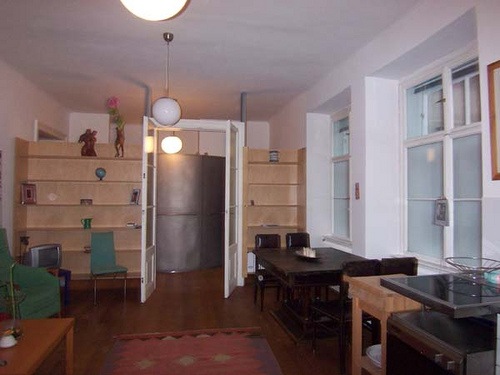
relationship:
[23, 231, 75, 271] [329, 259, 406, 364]
television on table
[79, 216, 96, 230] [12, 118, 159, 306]
pitcher sitting on bookcase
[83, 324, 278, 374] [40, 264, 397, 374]
rug on floor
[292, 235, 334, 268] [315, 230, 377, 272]
candles on table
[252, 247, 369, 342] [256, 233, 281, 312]
table and chair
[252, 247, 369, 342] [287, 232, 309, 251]
table and chair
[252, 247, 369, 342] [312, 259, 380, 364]
table and chair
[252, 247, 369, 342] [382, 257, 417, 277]
table and chair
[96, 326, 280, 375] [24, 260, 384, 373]
rug on floor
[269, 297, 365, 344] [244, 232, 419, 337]
dark rug under diningroom table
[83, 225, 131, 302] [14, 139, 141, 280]
chair in front of bookcase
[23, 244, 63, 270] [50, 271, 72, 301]
television on table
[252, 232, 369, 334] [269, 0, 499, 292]
table against wall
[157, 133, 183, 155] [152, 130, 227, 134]
globe light hanging from ceiling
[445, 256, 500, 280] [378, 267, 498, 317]
basket on top of counter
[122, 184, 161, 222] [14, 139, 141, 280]
picture frame on bookcase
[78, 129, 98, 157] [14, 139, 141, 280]
sculpture on bookcase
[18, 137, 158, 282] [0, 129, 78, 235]
shelf on wall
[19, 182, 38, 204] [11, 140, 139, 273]
picture frame on shelf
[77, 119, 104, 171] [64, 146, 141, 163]
sculpture on shelf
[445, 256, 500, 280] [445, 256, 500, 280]
basket made of basket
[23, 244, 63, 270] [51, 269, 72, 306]
television sitting on table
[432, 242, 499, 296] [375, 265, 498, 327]
basket on counter